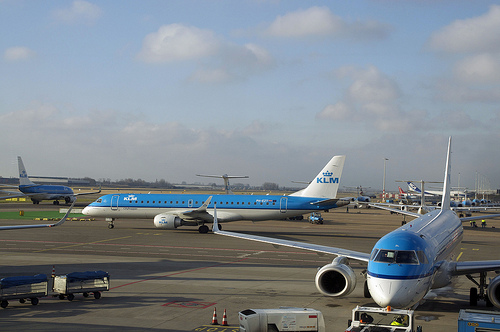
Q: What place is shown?
A: It is a runway.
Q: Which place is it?
A: It is a runway.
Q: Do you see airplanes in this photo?
A: Yes, there are airplanes.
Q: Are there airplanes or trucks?
A: Yes, there are airplanes.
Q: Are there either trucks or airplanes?
A: Yes, there are airplanes.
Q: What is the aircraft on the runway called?
A: The aircraft is airplanes.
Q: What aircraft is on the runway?
A: The aircraft is airplanes.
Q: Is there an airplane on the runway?
A: Yes, there are airplanes on the runway.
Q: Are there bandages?
A: No, there are no bandages.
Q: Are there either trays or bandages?
A: No, there are no bandages or trays.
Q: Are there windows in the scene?
A: Yes, there is a window.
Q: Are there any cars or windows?
A: Yes, there is a window.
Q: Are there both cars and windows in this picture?
A: No, there is a window but no cars.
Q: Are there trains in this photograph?
A: No, there are no trains.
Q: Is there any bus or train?
A: No, there are no trains or buses.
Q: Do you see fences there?
A: No, there are no fences.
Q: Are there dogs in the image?
A: No, there are no dogs.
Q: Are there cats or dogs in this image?
A: No, there are no dogs or cats.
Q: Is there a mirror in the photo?
A: No, there are no mirrors.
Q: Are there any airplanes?
A: Yes, there is an airplane.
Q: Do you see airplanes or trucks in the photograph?
A: Yes, there is an airplane.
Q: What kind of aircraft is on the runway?
A: The aircraft is an airplane.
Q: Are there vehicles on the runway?
A: No, there is an airplane on the runway.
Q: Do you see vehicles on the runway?
A: No, there is an airplane on the runway.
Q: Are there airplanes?
A: Yes, there is an airplane.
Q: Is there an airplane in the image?
A: Yes, there is an airplane.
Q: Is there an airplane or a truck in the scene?
A: Yes, there is an airplane.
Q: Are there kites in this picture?
A: No, there are no kites.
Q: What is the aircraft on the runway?
A: The aircraft is an airplane.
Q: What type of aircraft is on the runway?
A: The aircraft is an airplane.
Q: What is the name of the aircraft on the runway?
A: The aircraft is an airplane.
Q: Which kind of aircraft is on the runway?
A: The aircraft is an airplane.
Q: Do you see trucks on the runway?
A: No, there is an airplane on the runway.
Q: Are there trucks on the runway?
A: No, there is an airplane on the runway.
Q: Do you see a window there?
A: Yes, there is a window.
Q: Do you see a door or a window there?
A: Yes, there is a window.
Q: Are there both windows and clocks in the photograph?
A: No, there is a window but no clocks.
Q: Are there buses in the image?
A: No, there are no buses.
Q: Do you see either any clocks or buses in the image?
A: No, there are no buses or clocks.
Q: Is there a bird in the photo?
A: No, there are no birds.